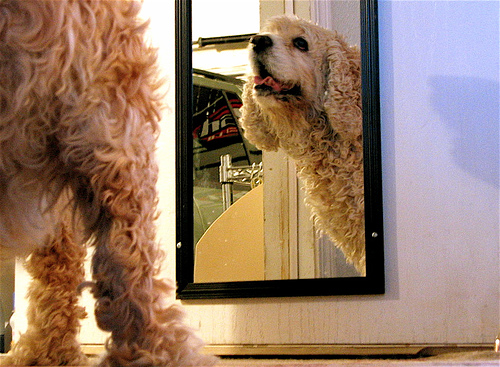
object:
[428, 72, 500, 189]
shadow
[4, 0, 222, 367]
dog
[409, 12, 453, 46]
wall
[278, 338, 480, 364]
baseboard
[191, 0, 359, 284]
mirror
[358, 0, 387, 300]
frame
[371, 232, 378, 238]
nails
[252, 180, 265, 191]
corner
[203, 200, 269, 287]
table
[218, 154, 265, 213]
shelf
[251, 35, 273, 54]
nose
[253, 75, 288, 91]
tongue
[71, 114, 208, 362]
legs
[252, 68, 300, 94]
mouth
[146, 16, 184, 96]
sunlight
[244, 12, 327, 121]
head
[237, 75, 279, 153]
right ear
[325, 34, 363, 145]
left ear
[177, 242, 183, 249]
nail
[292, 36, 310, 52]
eye